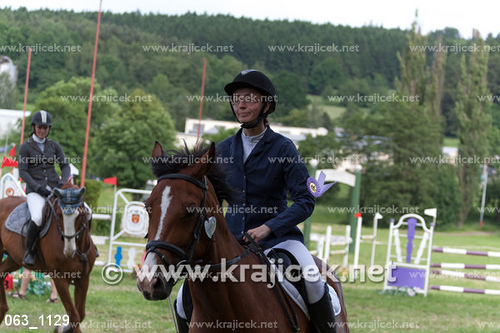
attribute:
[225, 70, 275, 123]
helmet — Black 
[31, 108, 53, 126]
helmet — Black, white 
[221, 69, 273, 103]
helmet — black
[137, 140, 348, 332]
horse — brown, horizontal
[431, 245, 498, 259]
pole — striped, white, purple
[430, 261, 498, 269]
pole — striped, white, purple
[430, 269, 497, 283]
pole — striped, white, purple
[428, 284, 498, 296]
pole — striped, white, purple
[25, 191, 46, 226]
pants — white 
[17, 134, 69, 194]
jacket — grey, rider's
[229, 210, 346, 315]
pants — white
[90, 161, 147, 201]
flag — red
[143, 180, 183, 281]
markings — white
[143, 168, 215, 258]
something — STRANGE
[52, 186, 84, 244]
something — STRANGE